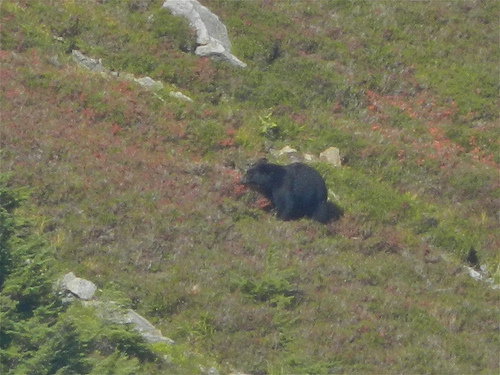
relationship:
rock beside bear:
[148, 0, 250, 68] [239, 157, 330, 225]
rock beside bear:
[278, 143, 298, 156] [239, 157, 330, 225]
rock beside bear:
[69, 47, 191, 106] [239, 157, 330, 225]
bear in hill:
[239, 157, 330, 225] [0, 0, 500, 375]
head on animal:
[232, 152, 282, 187] [234, 156, 343, 220]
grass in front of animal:
[2, 43, 499, 373] [240, 153, 349, 223]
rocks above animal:
[64, 44, 196, 104] [240, 153, 349, 223]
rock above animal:
[53, 267, 101, 301] [234, 156, 343, 220]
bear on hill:
[240, 155, 351, 223] [0, 0, 500, 372]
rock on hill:
[148, 0, 250, 68] [0, 0, 500, 372]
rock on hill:
[318, 145, 344, 166] [0, 0, 500, 372]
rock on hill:
[302, 152, 320, 164] [0, 0, 500, 372]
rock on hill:
[58, 268, 175, 354] [0, 0, 500, 372]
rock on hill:
[69, 47, 191, 106] [0, 0, 500, 372]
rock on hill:
[53, 268, 178, 362] [0, 0, 500, 372]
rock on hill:
[270, 142, 321, 160] [0, 0, 500, 372]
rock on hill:
[66, 43, 196, 103] [0, 0, 500, 372]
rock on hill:
[53, 267, 173, 349] [0, 0, 500, 372]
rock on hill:
[154, 0, 247, 65] [0, 0, 500, 372]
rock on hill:
[317, 141, 341, 165] [0, 0, 500, 372]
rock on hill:
[268, 142, 321, 169] [0, 0, 500, 372]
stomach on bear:
[284, 188, 318, 216] [238, 155, 343, 229]